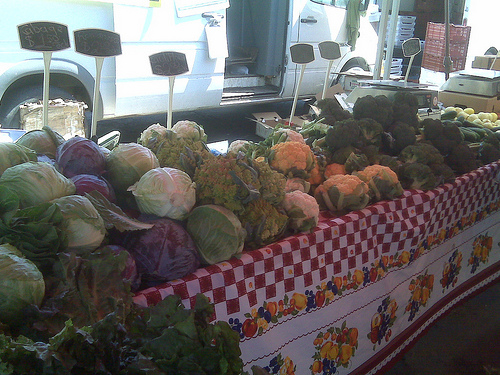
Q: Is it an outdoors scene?
A: Yes, it is outdoors.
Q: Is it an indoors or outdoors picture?
A: It is outdoors.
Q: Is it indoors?
A: No, it is outdoors.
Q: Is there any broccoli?
A: Yes, there is broccoli.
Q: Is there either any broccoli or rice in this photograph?
A: Yes, there is broccoli.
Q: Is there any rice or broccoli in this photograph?
A: Yes, there is broccoli.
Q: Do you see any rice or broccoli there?
A: Yes, there is broccoli.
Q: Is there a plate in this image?
A: No, there are no plates.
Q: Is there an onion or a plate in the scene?
A: No, there are no plates or onions.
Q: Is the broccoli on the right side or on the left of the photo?
A: The broccoli is on the right of the image.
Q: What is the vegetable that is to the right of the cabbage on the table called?
A: The vegetable is broccoli.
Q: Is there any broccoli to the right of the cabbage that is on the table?
A: Yes, there is broccoli to the right of the cabbage.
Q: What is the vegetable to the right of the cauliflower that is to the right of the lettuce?
A: The vegetable is broccoli.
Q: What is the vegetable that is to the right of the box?
A: The vegetable is broccoli.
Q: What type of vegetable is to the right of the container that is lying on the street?
A: The vegetable is broccoli.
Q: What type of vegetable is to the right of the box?
A: The vegetable is broccoli.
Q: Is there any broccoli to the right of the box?
A: Yes, there is broccoli to the right of the box.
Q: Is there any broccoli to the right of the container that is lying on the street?
A: Yes, there is broccoli to the right of the box.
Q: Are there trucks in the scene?
A: Yes, there is a truck.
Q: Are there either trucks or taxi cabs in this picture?
A: Yes, there is a truck.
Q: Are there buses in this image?
A: No, there are no buses.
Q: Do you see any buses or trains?
A: No, there are no buses or trains.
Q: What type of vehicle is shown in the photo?
A: The vehicle is a truck.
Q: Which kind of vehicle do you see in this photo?
A: The vehicle is a truck.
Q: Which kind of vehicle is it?
A: The vehicle is a truck.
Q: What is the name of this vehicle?
A: This is a truck.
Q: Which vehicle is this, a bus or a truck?
A: This is a truck.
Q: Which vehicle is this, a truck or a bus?
A: This is a truck.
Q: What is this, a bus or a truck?
A: This is a truck.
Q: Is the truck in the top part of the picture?
A: Yes, the truck is in the top of the image.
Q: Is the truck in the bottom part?
A: No, the truck is in the top of the image.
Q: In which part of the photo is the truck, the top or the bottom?
A: The truck is in the top of the image.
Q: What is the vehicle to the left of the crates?
A: The vehicle is a truck.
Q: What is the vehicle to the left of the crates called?
A: The vehicle is a truck.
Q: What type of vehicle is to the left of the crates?
A: The vehicle is a truck.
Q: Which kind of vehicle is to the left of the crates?
A: The vehicle is a truck.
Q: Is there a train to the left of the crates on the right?
A: No, there is a truck to the left of the crates.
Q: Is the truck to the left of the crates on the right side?
A: Yes, the truck is to the left of the crates.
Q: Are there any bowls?
A: No, there are no bowls.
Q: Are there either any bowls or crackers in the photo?
A: No, there are no bowls or crackers.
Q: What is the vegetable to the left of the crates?
A: The vegetable is cauliflower.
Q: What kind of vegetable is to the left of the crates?
A: The vegetable is cauliflower.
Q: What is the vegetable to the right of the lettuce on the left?
A: The vegetable is cauliflower.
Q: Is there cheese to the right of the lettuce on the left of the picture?
A: No, there is cauliflower to the right of the lettuce.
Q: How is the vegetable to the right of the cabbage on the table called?
A: The vegetable is cauliflower.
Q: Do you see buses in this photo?
A: No, there are no buses.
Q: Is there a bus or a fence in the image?
A: No, there are no buses or fences.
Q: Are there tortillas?
A: No, there are no tortillas.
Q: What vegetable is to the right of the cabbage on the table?
A: The vegetable is cauliflower.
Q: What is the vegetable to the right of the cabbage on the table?
A: The vegetable is cauliflower.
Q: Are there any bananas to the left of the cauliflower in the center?
A: No, there is a cabbage to the left of the cauliflower.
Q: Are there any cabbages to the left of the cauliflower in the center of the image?
A: Yes, there is a cabbage to the left of the cauliflower.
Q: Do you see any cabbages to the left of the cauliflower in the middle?
A: Yes, there is a cabbage to the left of the cauliflower.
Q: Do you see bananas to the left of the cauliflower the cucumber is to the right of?
A: No, there is a cabbage to the left of the cauliflower.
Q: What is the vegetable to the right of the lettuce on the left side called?
A: The vegetable is a cabbage.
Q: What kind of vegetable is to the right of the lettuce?
A: The vegetable is a cabbage.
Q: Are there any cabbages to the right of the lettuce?
A: Yes, there is a cabbage to the right of the lettuce.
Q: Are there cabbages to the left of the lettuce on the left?
A: No, the cabbage is to the right of the lettuce.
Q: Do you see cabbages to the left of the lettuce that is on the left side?
A: No, the cabbage is to the right of the lettuce.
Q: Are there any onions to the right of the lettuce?
A: No, there is a cabbage to the right of the lettuce.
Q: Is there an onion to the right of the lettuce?
A: No, there is a cabbage to the right of the lettuce.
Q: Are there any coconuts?
A: No, there are no coconuts.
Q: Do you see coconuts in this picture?
A: No, there are no coconuts.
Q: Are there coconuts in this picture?
A: No, there are no coconuts.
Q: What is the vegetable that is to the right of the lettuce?
A: The vegetable is a cabbage.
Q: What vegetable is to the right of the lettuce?
A: The vegetable is a cabbage.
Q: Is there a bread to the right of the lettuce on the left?
A: No, there is a cabbage to the right of the lettuce.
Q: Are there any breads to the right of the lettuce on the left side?
A: No, there is a cabbage to the right of the lettuce.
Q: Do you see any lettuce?
A: Yes, there is lettuce.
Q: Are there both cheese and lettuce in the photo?
A: No, there is lettuce but no cheese.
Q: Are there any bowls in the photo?
A: No, there are no bowls.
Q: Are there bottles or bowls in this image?
A: No, there are no bowls or bottles.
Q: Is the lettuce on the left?
A: Yes, the lettuce is on the left of the image.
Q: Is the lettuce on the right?
A: No, the lettuce is on the left of the image.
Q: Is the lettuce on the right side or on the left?
A: The lettuce is on the left of the image.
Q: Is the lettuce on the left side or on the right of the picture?
A: The lettuce is on the left of the image.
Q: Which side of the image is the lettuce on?
A: The lettuce is on the left of the image.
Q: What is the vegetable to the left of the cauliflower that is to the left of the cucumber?
A: The vegetable is lettuce.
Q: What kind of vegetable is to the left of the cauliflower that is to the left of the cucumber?
A: The vegetable is lettuce.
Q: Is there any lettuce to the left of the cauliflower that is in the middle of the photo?
A: Yes, there is lettuce to the left of the cauliflower.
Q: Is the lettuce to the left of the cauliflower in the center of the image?
A: Yes, the lettuce is to the left of the cauliflower.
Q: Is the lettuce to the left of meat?
A: No, the lettuce is to the left of the cauliflower.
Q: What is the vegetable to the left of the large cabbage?
A: The vegetable is lettuce.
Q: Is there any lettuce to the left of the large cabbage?
A: Yes, there is lettuce to the left of the cabbage.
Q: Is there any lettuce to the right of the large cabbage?
A: No, the lettuce is to the left of the cabbage.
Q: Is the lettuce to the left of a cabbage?
A: Yes, the lettuce is to the left of a cabbage.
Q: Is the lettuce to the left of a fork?
A: No, the lettuce is to the left of a cabbage.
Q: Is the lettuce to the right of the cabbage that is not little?
A: No, the lettuce is to the left of the cabbage.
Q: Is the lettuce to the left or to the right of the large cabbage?
A: The lettuce is to the left of the cabbage.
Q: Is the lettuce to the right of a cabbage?
A: No, the lettuce is to the left of a cabbage.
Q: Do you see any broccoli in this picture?
A: Yes, there is broccoli.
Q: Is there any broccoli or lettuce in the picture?
A: Yes, there is broccoli.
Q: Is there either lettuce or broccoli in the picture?
A: Yes, there is broccoli.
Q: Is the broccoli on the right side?
A: Yes, the broccoli is on the right of the image.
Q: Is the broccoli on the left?
A: No, the broccoli is on the right of the image.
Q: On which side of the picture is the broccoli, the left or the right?
A: The broccoli is on the right of the image.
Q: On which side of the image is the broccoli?
A: The broccoli is on the right of the image.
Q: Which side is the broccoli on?
A: The broccoli is on the right of the image.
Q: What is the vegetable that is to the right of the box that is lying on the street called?
A: The vegetable is broccoli.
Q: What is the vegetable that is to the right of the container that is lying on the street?
A: The vegetable is broccoli.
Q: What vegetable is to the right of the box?
A: The vegetable is broccoli.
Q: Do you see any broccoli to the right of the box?
A: Yes, there is broccoli to the right of the box.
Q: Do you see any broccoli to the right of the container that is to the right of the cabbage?
A: Yes, there is broccoli to the right of the box.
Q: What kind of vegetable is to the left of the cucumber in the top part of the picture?
A: The vegetable is broccoli.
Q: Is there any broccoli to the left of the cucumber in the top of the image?
A: Yes, there is broccoli to the left of the cucumber.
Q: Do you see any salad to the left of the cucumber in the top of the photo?
A: No, there is broccoli to the left of the cucumber.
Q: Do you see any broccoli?
A: Yes, there is broccoli.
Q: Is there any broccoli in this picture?
A: Yes, there is broccoli.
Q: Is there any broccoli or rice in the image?
A: Yes, there is broccoli.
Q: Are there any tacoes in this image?
A: No, there are no tacoes.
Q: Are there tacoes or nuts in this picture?
A: No, there are no tacoes or nuts.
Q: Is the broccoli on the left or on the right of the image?
A: The broccoli is on the right of the image.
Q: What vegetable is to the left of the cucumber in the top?
A: The vegetable is broccoli.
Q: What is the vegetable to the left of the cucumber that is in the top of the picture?
A: The vegetable is broccoli.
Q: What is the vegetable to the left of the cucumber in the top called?
A: The vegetable is broccoli.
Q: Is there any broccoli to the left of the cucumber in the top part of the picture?
A: Yes, there is broccoli to the left of the cucumber.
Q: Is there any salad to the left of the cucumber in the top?
A: No, there is broccoli to the left of the cucumber.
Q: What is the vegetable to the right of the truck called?
A: The vegetable is broccoli.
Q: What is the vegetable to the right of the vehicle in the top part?
A: The vegetable is broccoli.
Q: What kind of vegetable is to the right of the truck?
A: The vegetable is broccoli.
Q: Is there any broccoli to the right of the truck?
A: Yes, there is broccoli to the right of the truck.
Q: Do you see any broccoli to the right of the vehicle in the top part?
A: Yes, there is broccoli to the right of the truck.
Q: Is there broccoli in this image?
A: Yes, there is broccoli.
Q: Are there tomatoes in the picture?
A: No, there are no tomatoes.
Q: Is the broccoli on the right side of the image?
A: Yes, the broccoli is on the right of the image.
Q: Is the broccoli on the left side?
A: No, the broccoli is on the right of the image.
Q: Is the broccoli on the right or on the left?
A: The broccoli is on the right of the image.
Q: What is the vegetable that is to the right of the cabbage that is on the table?
A: The vegetable is broccoli.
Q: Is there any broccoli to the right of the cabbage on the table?
A: Yes, there is broccoli to the right of the cabbage.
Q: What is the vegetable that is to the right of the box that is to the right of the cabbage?
A: The vegetable is broccoli.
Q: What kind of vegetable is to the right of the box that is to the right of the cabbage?
A: The vegetable is broccoli.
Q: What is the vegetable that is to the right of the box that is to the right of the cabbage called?
A: The vegetable is broccoli.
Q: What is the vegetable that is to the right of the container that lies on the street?
A: The vegetable is broccoli.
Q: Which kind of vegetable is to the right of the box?
A: The vegetable is broccoli.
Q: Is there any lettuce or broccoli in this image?
A: Yes, there is broccoli.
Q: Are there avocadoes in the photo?
A: No, there are no avocadoes.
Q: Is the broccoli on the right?
A: Yes, the broccoli is on the right of the image.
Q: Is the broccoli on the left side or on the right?
A: The broccoli is on the right of the image.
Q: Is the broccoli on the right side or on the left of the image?
A: The broccoli is on the right of the image.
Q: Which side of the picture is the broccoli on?
A: The broccoli is on the right of the image.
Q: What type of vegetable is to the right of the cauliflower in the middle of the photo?
A: The vegetable is broccoli.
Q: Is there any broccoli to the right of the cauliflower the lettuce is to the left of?
A: Yes, there is broccoli to the right of the cauliflower.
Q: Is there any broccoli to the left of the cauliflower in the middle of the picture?
A: No, the broccoli is to the right of the cauliflower.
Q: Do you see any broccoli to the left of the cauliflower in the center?
A: No, the broccoli is to the right of the cauliflower.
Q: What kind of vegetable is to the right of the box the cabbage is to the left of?
A: The vegetable is broccoli.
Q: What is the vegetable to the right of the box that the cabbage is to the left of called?
A: The vegetable is broccoli.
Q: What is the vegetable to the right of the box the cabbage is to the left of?
A: The vegetable is broccoli.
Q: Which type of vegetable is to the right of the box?
A: The vegetable is broccoli.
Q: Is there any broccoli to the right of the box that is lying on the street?
A: Yes, there is broccoli to the right of the box.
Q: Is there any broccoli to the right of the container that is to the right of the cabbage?
A: Yes, there is broccoli to the right of the box.